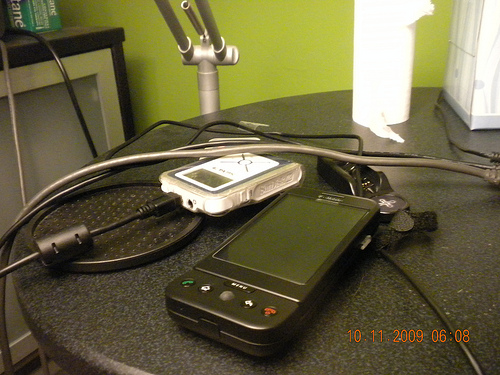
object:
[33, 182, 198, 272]
charger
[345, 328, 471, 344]
date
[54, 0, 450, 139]
wall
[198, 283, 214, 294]
button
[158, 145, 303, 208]
device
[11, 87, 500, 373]
table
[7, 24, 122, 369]
cabinet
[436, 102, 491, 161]
wires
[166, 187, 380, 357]
cellphone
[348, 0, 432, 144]
towels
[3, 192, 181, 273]
cord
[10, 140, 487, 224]
cord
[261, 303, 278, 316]
button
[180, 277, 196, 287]
button